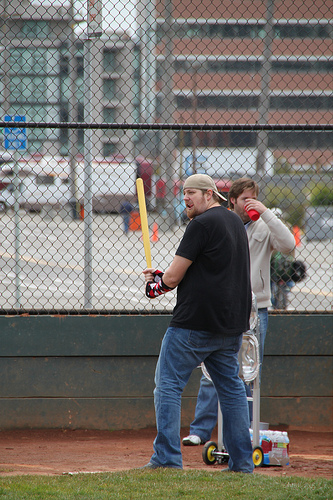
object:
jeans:
[150, 322, 258, 474]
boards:
[0, 312, 332, 429]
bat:
[136, 176, 152, 278]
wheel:
[250, 444, 264, 469]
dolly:
[206, 290, 275, 474]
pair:
[148, 310, 271, 474]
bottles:
[259, 430, 273, 467]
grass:
[0, 465, 331, 500]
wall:
[0, 307, 331, 435]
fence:
[0, 2, 333, 312]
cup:
[244, 204, 260, 221]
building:
[0, 1, 332, 224]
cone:
[151, 220, 159, 243]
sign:
[1, 114, 28, 154]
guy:
[140, 169, 255, 478]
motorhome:
[3, 151, 143, 220]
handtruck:
[201, 289, 270, 466]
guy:
[184, 178, 294, 446]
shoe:
[184, 432, 206, 449]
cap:
[184, 173, 227, 203]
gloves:
[145, 278, 175, 301]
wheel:
[201, 439, 216, 466]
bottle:
[273, 430, 289, 467]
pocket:
[184, 323, 212, 350]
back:
[181, 204, 252, 332]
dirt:
[0, 424, 333, 476]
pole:
[79, 0, 108, 168]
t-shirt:
[172, 199, 253, 338]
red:
[243, 206, 262, 224]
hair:
[229, 174, 259, 203]